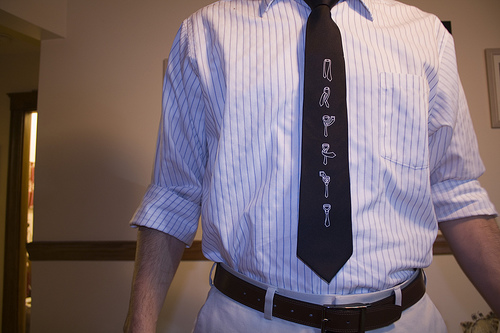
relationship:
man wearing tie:
[202, 29, 462, 304] [306, 29, 353, 228]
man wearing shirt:
[202, 29, 462, 304] [229, 49, 299, 251]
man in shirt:
[202, 29, 462, 304] [229, 49, 299, 251]